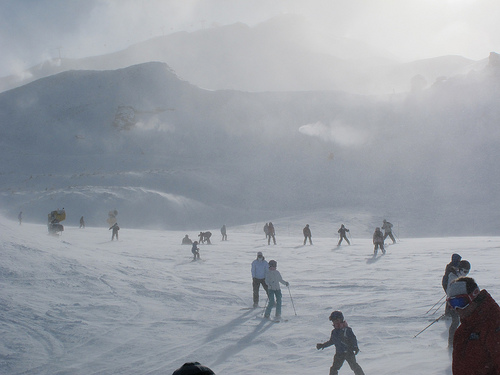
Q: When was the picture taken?
A: Day time.